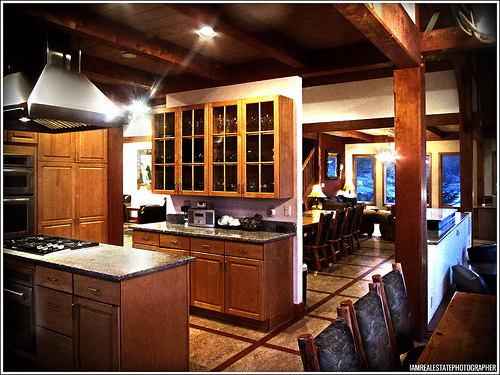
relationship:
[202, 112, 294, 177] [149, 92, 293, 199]
glass door on cabinet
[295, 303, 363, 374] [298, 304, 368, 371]
back on chair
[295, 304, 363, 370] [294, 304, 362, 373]
back on chair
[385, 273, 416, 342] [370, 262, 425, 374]
back on chair